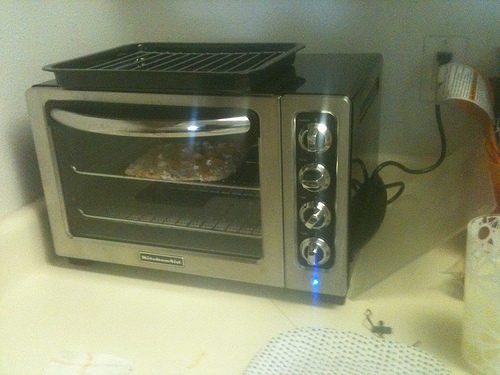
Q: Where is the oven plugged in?
A: Top plug.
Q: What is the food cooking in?
A: Toaster oven.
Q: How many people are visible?
A: Zero.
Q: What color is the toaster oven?
A: Chrome.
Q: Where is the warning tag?
A: On the cord.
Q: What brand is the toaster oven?
A: KitchenAid.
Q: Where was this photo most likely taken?
A: Kitchen.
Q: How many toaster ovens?
A: 1.